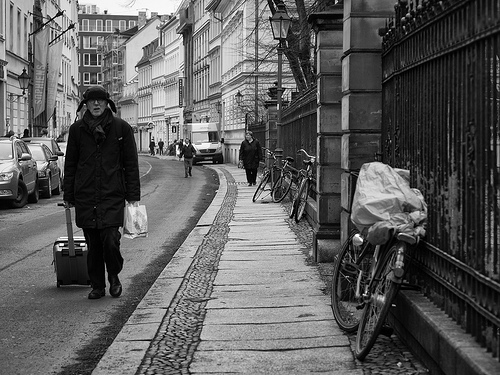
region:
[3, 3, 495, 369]
pedestrians in the city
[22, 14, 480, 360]
pedestrians walking in the city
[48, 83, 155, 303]
man in hat with earflaps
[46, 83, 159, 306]
man walking and pulling luggage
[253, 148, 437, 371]
bicycles against the fence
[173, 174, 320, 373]
sidewalk in the city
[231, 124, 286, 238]
pedestrian on the sidewalk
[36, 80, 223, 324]
two pedestrians walking in the street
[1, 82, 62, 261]
cars parked along the street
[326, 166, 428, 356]
a parked bicycle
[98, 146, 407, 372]
a long paved city sidewalk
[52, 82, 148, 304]
a man walking on street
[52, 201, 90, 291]
a piece of luggage with handle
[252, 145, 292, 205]
a parked bicycle on sidewalk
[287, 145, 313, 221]
a parked bicycle on sidewalk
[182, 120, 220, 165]
a parked commercial vehicle on sidewalk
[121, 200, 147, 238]
a small white bag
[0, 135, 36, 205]
a small parked car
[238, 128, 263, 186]
a pedestrian on sidewalk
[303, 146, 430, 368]
bicycle leaning on metal fencing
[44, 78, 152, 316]
man walking in street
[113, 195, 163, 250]
white bag in hand of man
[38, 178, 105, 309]
wheeled luggage being pulled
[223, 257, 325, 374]
stone sidewalk tiles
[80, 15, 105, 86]
windows on side of building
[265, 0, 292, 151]
metal street light on sidewalk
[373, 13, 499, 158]
black metal fence bars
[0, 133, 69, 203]
row of parked cars on side of road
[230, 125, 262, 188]
person walking on sidewalk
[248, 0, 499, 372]
The bike is leaning against the fence.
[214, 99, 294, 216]
The woman is walking.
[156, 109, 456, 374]
The woman is on the sidewalk.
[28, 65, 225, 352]
The man is pulling luggage.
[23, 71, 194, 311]
The man is walking.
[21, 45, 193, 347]
The man is carrying a bag.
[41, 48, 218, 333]
The man is in the street.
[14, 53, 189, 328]
The man is wearing a hat.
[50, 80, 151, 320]
woman walking in street